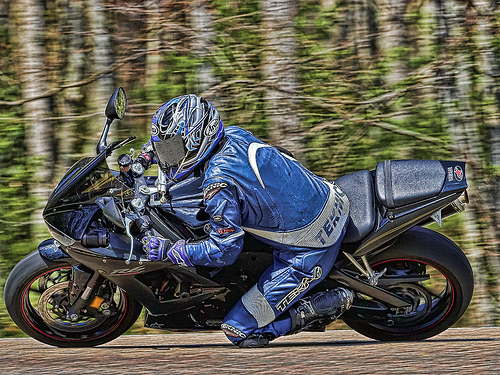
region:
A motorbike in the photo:
[2, 91, 484, 349]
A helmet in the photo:
[145, 94, 224, 171]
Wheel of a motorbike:
[0, 256, 156, 343]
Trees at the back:
[261, 49, 411, 159]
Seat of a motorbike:
[331, 161, 392, 239]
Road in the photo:
[234, 347, 319, 373]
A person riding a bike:
[7, 94, 468, 351]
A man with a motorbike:
[166, 100, 356, 337]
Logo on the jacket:
[241, 129, 284, 189]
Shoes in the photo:
[298, 284, 355, 329]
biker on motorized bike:
[8, 79, 486, 349]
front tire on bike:
[10, 230, 176, 362]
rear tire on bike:
[341, 222, 481, 347]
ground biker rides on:
[13, 335, 493, 368]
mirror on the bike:
[101, 87, 153, 136]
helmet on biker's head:
[145, 83, 220, 175]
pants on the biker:
[234, 250, 333, 339]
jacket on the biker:
[184, 146, 341, 258]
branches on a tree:
[346, 58, 488, 138]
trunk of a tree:
[431, 85, 496, 322]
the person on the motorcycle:
[18, 82, 464, 348]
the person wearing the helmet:
[133, 95, 234, 172]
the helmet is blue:
[130, 94, 232, 190]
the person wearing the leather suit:
[169, 120, 360, 322]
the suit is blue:
[140, 131, 358, 335]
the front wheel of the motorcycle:
[0, 238, 142, 346]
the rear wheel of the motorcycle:
[347, 240, 472, 352]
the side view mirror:
[94, 81, 135, 121]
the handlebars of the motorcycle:
[117, 128, 157, 270]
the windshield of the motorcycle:
[52, 128, 134, 215]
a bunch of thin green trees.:
[267, 0, 402, 92]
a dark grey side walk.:
[303, 347, 398, 372]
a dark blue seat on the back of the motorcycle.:
[340, 154, 475, 247]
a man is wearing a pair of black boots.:
[284, 286, 359, 336]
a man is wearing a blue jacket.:
[242, 157, 285, 214]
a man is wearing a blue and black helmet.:
[142, 91, 223, 182]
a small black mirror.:
[94, 83, 130, 148]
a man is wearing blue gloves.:
[136, 227, 191, 274]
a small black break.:
[107, 132, 139, 158]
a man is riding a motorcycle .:
[1, 82, 482, 371]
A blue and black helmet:
[150, 95, 225, 184]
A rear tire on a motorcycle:
[341, 225, 473, 342]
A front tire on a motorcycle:
[3, 250, 143, 347]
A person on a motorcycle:
[5, 87, 475, 349]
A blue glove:
[142, 232, 172, 265]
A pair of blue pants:
[223, 227, 346, 347]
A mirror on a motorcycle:
[106, 90, 125, 115]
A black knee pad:
[236, 335, 269, 343]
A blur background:
[1, 0, 498, 334]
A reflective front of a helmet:
[151, 138, 186, 165]